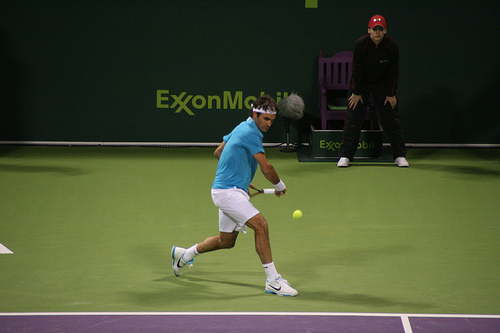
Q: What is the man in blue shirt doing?
A: Playing tennis.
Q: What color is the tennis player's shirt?
A: Blue.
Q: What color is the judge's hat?
A: Red.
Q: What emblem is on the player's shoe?
A: Nike.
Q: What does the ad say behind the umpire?
A: Exxon Mobil.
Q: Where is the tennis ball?
A: In the air.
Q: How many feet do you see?
A: 4.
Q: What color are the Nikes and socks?
A: White.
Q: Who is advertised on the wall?
A: Exxon.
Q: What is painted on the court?
A: White line.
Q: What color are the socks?
A: White.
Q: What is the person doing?
A: Playing tennis.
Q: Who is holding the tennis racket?
A: The tennis player.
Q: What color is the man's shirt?
A: Blue.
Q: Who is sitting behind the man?
A: The tennis judge.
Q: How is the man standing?
A: Legs apart.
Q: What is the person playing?
A: Tennis.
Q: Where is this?
A: Tennis court.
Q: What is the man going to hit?
A: Tennis ball.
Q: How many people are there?
A: Two.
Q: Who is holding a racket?
A: The player.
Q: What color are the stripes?
A: White.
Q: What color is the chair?
A: Purple.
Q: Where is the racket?
A: The man's hands.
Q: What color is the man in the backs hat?
A: Red.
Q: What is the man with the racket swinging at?
A: A ball.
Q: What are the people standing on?
A: A court.